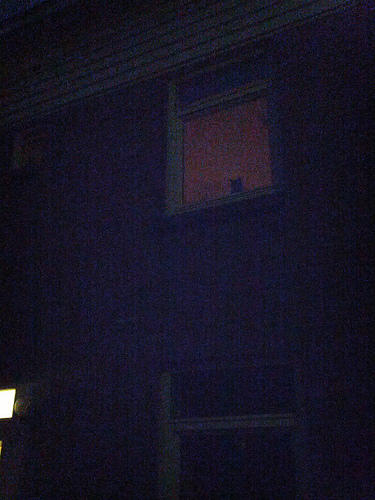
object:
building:
[0, 1, 375, 494]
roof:
[1, 0, 373, 114]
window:
[169, 91, 277, 210]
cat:
[231, 177, 243, 193]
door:
[163, 362, 313, 499]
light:
[0, 390, 14, 418]